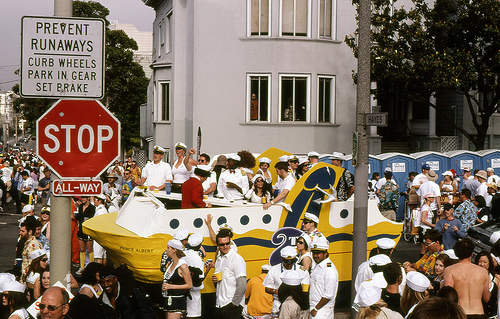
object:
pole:
[44, 0, 74, 318]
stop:
[43, 123, 115, 155]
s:
[43, 124, 61, 155]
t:
[60, 123, 77, 155]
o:
[76, 122, 95, 154]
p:
[93, 124, 115, 154]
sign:
[49, 179, 104, 196]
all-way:
[56, 182, 99, 194]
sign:
[20, 15, 107, 100]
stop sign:
[35, 99, 120, 179]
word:
[29, 38, 94, 52]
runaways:
[28, 38, 94, 53]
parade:
[99, 140, 421, 308]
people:
[403, 228, 449, 293]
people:
[240, 170, 274, 211]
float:
[77, 145, 410, 288]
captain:
[134, 144, 175, 197]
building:
[137, 0, 499, 174]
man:
[440, 240, 493, 318]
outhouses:
[314, 148, 499, 221]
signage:
[363, 111, 390, 126]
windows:
[243, 74, 341, 125]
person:
[205, 230, 250, 318]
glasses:
[218, 242, 232, 246]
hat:
[150, 144, 172, 153]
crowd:
[0, 128, 499, 318]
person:
[303, 242, 342, 319]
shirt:
[307, 256, 339, 319]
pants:
[307, 299, 336, 319]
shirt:
[178, 176, 212, 209]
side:
[321, 122, 494, 159]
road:
[0, 157, 499, 318]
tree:
[346, 0, 499, 156]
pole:
[349, 0, 373, 319]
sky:
[0, 0, 56, 40]